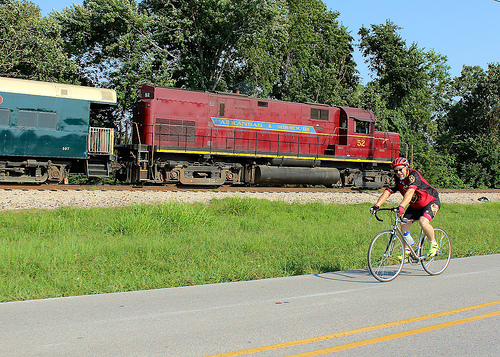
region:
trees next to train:
[142, 3, 332, 86]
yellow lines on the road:
[373, 298, 449, 355]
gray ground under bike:
[288, 282, 345, 334]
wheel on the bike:
[361, 228, 411, 280]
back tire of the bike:
[416, 223, 456, 275]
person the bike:
[355, 140, 460, 258]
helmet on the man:
[387, 153, 418, 185]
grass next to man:
[211, 225, 315, 275]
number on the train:
[350, 133, 375, 152]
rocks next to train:
[129, 188, 208, 209]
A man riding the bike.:
[360, 153, 470, 283]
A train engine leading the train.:
[137, 66, 405, 193]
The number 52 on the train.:
[351, 136, 366, 147]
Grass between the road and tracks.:
[27, 223, 359, 262]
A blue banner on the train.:
[211, 114, 316, 141]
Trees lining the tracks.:
[34, 11, 409, 95]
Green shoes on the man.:
[423, 238, 440, 256]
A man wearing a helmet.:
[390, 158, 415, 188]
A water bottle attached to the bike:
[402, 230, 416, 242]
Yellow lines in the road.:
[271, 295, 479, 355]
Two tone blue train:
[1, 89, 123, 198]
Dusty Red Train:
[133, 75, 411, 193]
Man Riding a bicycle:
[366, 155, 454, 280]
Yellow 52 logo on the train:
[355, 135, 365, 149]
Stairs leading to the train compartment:
[82, 125, 117, 180]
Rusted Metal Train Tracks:
[2, 174, 497, 201]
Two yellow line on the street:
[202, 293, 496, 355]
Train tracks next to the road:
[0, 0, 496, 355]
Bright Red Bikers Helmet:
[390, 157, 411, 179]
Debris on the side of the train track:
[470, 190, 497, 217]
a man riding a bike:
[357, 139, 462, 282]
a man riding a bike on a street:
[333, 144, 473, 306]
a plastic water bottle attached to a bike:
[394, 224, 420, 254]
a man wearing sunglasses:
[371, 157, 417, 200]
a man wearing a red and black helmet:
[388, 155, 414, 172]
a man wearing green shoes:
[420, 235, 445, 263]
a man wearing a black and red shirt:
[379, 161, 449, 202]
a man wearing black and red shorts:
[389, 191, 446, 234]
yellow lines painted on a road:
[272, 300, 477, 355]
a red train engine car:
[121, 67, 423, 202]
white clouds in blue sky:
[355, 0, 393, 27]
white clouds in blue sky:
[405, 11, 427, 31]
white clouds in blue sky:
[439, 4, 457, 49]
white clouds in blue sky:
[437, 19, 475, 47]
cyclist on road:
[353, 157, 443, 282]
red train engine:
[151, 67, 390, 173]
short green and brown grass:
[22, 210, 85, 240]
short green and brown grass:
[34, 242, 96, 292]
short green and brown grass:
[134, 228, 210, 268]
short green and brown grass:
[251, 210, 290, 251]